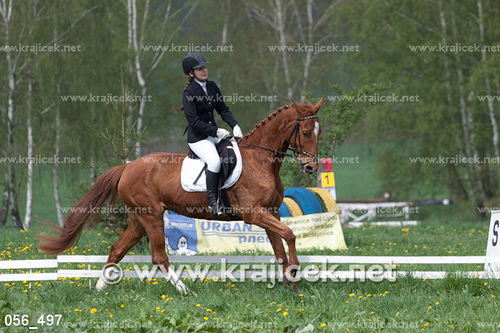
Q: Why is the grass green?
A: Rain.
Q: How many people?
A: One.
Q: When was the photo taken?
A: Day time.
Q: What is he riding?
A: A horse.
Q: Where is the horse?
A: Equestrain track.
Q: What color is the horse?
A: Brown.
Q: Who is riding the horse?
A: A man.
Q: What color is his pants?
A: White.